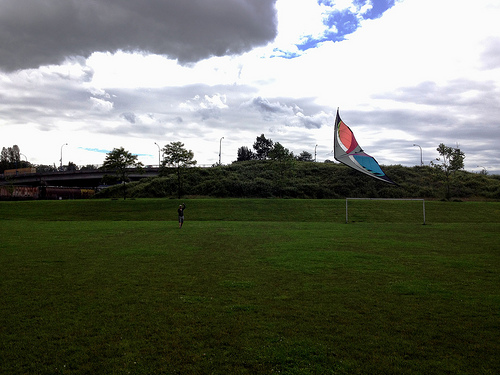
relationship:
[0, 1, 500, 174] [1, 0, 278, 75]
sky has cloud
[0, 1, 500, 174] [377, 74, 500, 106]
sky has cloud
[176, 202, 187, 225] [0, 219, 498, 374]
person on top of soccer field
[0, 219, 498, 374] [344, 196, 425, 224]
soccer field has goal net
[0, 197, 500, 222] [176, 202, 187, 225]
slope behind person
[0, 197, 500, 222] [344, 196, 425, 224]
slope behind goal net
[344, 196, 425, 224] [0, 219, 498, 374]
goal net on top of soccer field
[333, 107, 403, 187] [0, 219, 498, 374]
kite above soccer field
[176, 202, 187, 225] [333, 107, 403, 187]
person flying kite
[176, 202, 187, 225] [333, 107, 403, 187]
person has kite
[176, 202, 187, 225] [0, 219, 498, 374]
person running on soccer field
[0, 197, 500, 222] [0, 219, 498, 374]
slope behind soccer field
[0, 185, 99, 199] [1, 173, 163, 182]
train under bridge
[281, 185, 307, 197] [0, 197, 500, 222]
shrub on top of slope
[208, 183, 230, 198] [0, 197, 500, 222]
shrub on top of slope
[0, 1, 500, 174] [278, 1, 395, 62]
sky has opening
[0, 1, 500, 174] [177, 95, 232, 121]
sky has cloud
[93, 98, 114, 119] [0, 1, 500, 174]
cloud in sky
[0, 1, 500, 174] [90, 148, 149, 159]
sky has opening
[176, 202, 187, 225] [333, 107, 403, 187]
person holding kite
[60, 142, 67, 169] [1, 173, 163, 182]
streetlight on bridge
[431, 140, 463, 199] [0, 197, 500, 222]
tree on top of slope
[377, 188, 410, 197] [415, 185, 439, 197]
shrub near shrub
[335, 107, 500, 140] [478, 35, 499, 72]
cloud below cloud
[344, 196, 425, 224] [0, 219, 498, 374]
goal net on soccer field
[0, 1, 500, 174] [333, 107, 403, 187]
sky above kite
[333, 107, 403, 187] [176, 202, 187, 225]
kite above person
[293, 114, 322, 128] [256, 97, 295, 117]
cloud below cloud